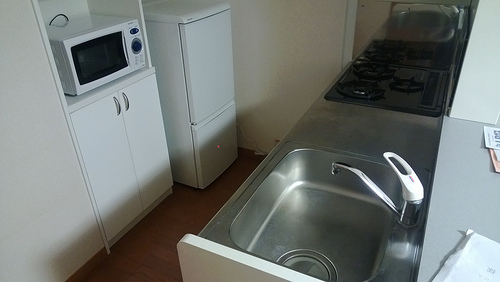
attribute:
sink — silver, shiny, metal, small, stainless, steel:
[230, 148, 412, 277]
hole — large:
[285, 253, 329, 281]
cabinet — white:
[72, 76, 177, 241]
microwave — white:
[45, 16, 151, 94]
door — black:
[72, 33, 128, 82]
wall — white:
[231, 4, 346, 167]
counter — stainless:
[418, 115, 499, 279]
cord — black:
[49, 13, 70, 25]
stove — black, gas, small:
[326, 59, 444, 113]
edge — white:
[175, 234, 315, 279]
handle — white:
[383, 151, 423, 201]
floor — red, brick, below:
[66, 147, 267, 277]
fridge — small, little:
[146, 3, 238, 189]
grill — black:
[338, 78, 383, 101]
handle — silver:
[114, 97, 123, 113]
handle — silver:
[122, 92, 131, 111]